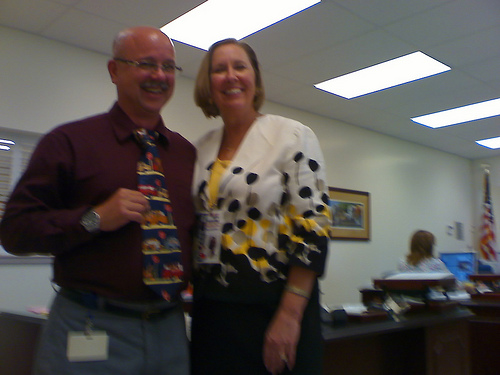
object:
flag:
[477, 172, 497, 264]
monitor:
[438, 252, 477, 283]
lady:
[397, 229, 464, 294]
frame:
[327, 185, 373, 242]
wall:
[1, 25, 474, 307]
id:
[67, 329, 109, 360]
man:
[0, 26, 197, 375]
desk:
[321, 307, 477, 375]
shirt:
[209, 158, 232, 209]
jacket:
[191, 113, 330, 294]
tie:
[133, 127, 186, 303]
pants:
[35, 283, 191, 373]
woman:
[189, 38, 332, 373]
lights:
[160, 0, 324, 52]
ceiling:
[0, 0, 499, 162]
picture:
[326, 198, 365, 231]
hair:
[193, 37, 265, 120]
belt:
[56, 286, 183, 321]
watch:
[79, 205, 104, 238]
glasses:
[110, 55, 183, 73]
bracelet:
[282, 282, 312, 301]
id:
[200, 209, 223, 264]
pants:
[190, 277, 324, 372]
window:
[1, 127, 56, 267]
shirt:
[1, 100, 197, 300]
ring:
[281, 356, 290, 364]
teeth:
[223, 88, 244, 96]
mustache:
[139, 80, 171, 91]